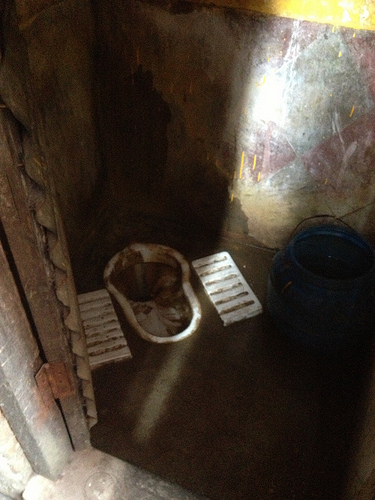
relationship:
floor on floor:
[191, 251, 264, 327] [72, 211, 374, 498]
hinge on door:
[31, 358, 76, 408] [4, 32, 85, 452]